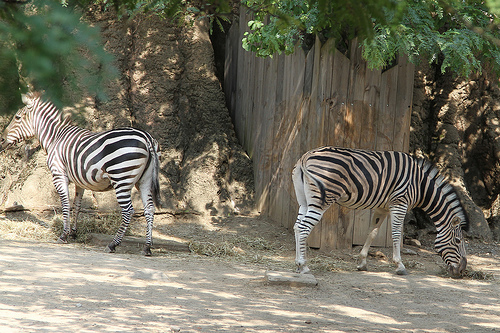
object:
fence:
[220, 6, 417, 255]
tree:
[238, 0, 500, 75]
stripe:
[305, 164, 354, 186]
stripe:
[298, 249, 305, 254]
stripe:
[308, 207, 324, 217]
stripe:
[303, 215, 318, 223]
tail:
[146, 133, 166, 211]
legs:
[101, 149, 137, 254]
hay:
[190, 231, 285, 263]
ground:
[0, 216, 500, 332]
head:
[1, 89, 53, 149]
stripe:
[100, 151, 150, 171]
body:
[42, 117, 166, 257]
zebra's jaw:
[4, 126, 34, 149]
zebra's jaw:
[430, 237, 452, 269]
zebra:
[0, 91, 166, 256]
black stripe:
[112, 181, 134, 190]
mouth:
[0, 140, 15, 152]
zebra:
[287, 147, 474, 277]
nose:
[453, 259, 471, 277]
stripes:
[394, 152, 406, 187]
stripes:
[309, 194, 333, 204]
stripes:
[388, 204, 406, 210]